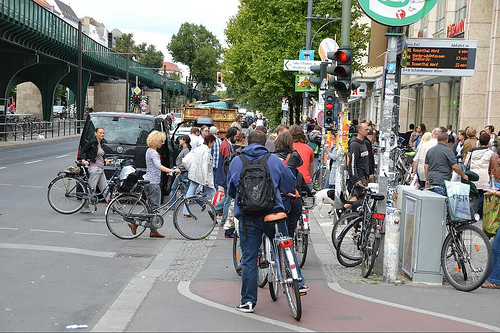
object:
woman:
[139, 130, 173, 240]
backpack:
[236, 153, 274, 217]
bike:
[336, 192, 388, 279]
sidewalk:
[192, 162, 498, 332]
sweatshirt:
[226, 143, 296, 219]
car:
[77, 111, 174, 197]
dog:
[116, 165, 139, 181]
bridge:
[2, 1, 201, 113]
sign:
[399, 48, 475, 70]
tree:
[221, 1, 367, 125]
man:
[422, 133, 468, 194]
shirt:
[287, 143, 315, 185]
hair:
[145, 130, 170, 149]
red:
[338, 54, 346, 61]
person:
[224, 128, 309, 308]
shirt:
[423, 146, 459, 184]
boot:
[150, 231, 164, 238]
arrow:
[284, 57, 290, 71]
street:
[0, 138, 499, 333]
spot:
[85, 217, 117, 224]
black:
[243, 202, 258, 214]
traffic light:
[331, 49, 350, 65]